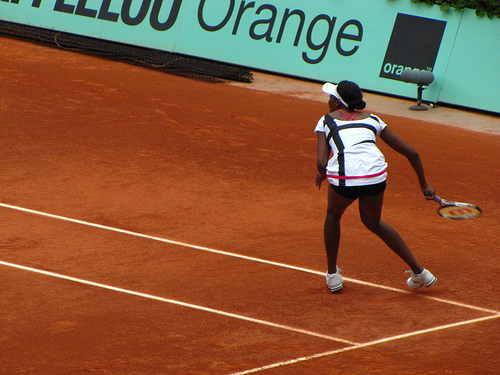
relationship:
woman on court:
[300, 87, 466, 290] [144, 122, 233, 200]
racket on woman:
[425, 181, 478, 232] [300, 87, 466, 290]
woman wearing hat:
[300, 87, 466, 290] [320, 79, 336, 102]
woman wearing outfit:
[300, 87, 466, 290] [325, 124, 389, 176]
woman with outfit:
[300, 87, 466, 290] [325, 124, 389, 176]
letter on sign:
[196, 4, 337, 60] [148, 13, 488, 91]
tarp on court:
[91, 46, 167, 75] [144, 122, 233, 200]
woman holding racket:
[300, 87, 466, 290] [425, 181, 478, 232]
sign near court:
[148, 13, 488, 91] [144, 122, 233, 200]